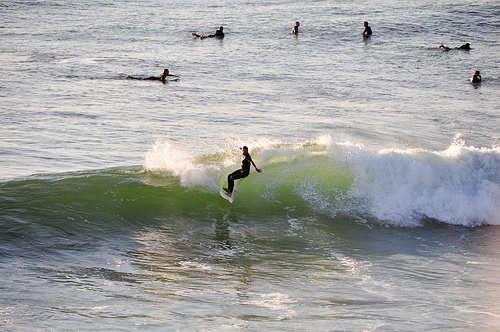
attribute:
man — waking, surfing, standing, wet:
[224, 145, 263, 195]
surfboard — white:
[219, 179, 234, 208]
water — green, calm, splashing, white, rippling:
[0, 0, 499, 330]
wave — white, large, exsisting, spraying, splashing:
[341, 141, 495, 227]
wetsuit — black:
[226, 158, 254, 192]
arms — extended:
[250, 158, 264, 175]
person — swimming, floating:
[119, 69, 187, 85]